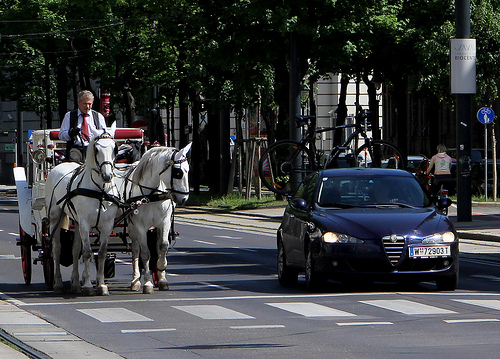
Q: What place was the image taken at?
A: It was taken at the road.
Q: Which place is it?
A: It is a road.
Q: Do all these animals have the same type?
A: Yes, all the animals are horses.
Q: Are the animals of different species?
A: No, all the animals are horses.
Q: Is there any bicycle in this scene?
A: Yes, there is a bicycle.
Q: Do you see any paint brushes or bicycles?
A: Yes, there is a bicycle.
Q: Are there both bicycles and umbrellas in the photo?
A: No, there is a bicycle but no umbrellas.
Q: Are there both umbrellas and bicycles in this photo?
A: No, there is a bicycle but no umbrellas.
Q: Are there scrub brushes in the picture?
A: No, there are no scrub brushes.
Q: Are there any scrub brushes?
A: No, there are no scrub brushes.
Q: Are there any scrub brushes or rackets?
A: No, there are no scrub brushes or rackets.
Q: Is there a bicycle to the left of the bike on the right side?
A: Yes, there is a bicycle to the left of the bike.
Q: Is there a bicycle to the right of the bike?
A: No, the bicycle is to the left of the bike.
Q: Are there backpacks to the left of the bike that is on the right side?
A: No, there is a bicycle to the left of the bike.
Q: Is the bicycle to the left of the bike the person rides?
A: Yes, the bicycle is to the left of the bike.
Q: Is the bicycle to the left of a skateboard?
A: No, the bicycle is to the left of the bike.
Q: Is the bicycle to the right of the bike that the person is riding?
A: No, the bicycle is to the left of the bike.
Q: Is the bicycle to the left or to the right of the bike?
A: The bicycle is to the left of the bike.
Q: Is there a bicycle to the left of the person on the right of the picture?
A: Yes, there is a bicycle to the left of the person.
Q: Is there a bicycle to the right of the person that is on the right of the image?
A: No, the bicycle is to the left of the person.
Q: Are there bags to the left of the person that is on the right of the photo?
A: No, there is a bicycle to the left of the person.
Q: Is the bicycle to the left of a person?
A: Yes, the bicycle is to the left of a person.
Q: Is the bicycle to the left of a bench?
A: No, the bicycle is to the left of a person.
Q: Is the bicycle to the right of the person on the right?
A: No, the bicycle is to the left of the person.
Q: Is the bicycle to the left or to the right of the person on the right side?
A: The bicycle is to the left of the person.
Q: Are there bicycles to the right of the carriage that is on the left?
A: Yes, there is a bicycle to the right of the carriage.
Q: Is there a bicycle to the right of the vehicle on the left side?
A: Yes, there is a bicycle to the right of the carriage.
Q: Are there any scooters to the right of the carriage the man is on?
A: No, there is a bicycle to the right of the carriage.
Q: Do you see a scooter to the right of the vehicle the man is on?
A: No, there is a bicycle to the right of the carriage.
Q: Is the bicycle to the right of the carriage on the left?
A: Yes, the bicycle is to the right of the carriage.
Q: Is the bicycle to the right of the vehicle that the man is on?
A: Yes, the bicycle is to the right of the carriage.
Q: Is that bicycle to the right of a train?
A: No, the bicycle is to the right of the carriage.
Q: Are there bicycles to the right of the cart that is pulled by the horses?
A: Yes, there is a bicycle to the right of the cart.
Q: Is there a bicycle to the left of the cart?
A: No, the bicycle is to the right of the cart.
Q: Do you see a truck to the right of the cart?
A: No, there is a bicycle to the right of the cart.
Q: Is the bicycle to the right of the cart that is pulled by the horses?
A: Yes, the bicycle is to the right of the cart.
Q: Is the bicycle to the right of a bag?
A: No, the bicycle is to the right of the cart.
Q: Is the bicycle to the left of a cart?
A: No, the bicycle is to the right of a cart.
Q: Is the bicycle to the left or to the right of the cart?
A: The bicycle is to the right of the cart.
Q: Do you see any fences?
A: No, there are no fences.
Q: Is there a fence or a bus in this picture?
A: No, there are no fences or buses.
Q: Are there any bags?
A: No, there are no bags.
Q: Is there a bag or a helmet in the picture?
A: No, there are no bags or helmets.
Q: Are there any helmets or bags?
A: No, there are no bags or helmets.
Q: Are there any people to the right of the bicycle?
A: Yes, there is a person to the right of the bicycle.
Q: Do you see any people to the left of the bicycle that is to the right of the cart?
A: No, the person is to the right of the bicycle.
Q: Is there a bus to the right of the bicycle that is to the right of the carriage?
A: No, there is a person to the right of the bicycle.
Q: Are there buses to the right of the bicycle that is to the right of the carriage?
A: No, there is a person to the right of the bicycle.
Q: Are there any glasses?
A: No, there are no glasses.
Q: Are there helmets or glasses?
A: No, there are no glasses or helmets.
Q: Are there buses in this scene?
A: No, there are no buses.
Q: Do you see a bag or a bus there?
A: No, there are no buses or bags.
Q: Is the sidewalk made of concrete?
A: Yes, the sidewalk is made of concrete.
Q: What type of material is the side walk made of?
A: The side walk is made of cement.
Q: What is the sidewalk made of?
A: The side walk is made of concrete.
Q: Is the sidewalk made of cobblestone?
A: No, the sidewalk is made of concrete.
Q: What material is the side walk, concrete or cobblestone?
A: The side walk is made of concrete.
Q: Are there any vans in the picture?
A: No, there are no vans.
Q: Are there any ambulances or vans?
A: No, there are no vans or ambulances.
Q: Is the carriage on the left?
A: Yes, the carriage is on the left of the image.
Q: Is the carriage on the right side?
A: No, the carriage is on the left of the image.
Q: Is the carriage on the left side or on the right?
A: The carriage is on the left of the image.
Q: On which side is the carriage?
A: The carriage is on the left of the image.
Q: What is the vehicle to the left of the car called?
A: The vehicle is a carriage.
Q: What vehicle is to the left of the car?
A: The vehicle is a carriage.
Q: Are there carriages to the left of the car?
A: Yes, there is a carriage to the left of the car.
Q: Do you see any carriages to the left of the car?
A: Yes, there is a carriage to the left of the car.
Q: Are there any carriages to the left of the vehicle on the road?
A: Yes, there is a carriage to the left of the car.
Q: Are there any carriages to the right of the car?
A: No, the carriage is to the left of the car.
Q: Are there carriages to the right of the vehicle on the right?
A: No, the carriage is to the left of the car.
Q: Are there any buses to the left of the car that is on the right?
A: No, there is a carriage to the left of the car.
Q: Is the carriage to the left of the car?
A: Yes, the carriage is to the left of the car.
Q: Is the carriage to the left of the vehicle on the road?
A: Yes, the carriage is to the left of the car.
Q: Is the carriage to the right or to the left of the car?
A: The carriage is to the left of the car.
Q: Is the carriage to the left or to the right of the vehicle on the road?
A: The carriage is to the left of the car.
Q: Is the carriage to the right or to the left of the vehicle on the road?
A: The carriage is to the left of the car.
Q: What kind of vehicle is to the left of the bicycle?
A: The vehicle is a carriage.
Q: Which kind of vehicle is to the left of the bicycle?
A: The vehicle is a carriage.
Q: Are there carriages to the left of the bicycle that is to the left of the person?
A: Yes, there is a carriage to the left of the bicycle.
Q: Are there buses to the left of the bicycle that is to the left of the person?
A: No, there is a carriage to the left of the bicycle.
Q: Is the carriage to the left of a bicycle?
A: Yes, the carriage is to the left of a bicycle.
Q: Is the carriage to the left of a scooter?
A: No, the carriage is to the left of a bicycle.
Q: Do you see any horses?
A: Yes, there are horses.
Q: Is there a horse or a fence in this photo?
A: Yes, there are horses.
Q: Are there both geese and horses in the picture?
A: No, there are horses but no geese.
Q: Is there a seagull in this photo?
A: No, there are no seagulls.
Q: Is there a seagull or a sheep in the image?
A: No, there are no seagulls or sheep.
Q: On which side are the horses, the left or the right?
A: The horses are on the left of the image.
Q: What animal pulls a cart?
A: The horses pull a cart.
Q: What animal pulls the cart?
A: The horses pull a cart.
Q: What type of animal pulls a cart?
A: The animals are horses.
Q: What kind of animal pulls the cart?
A: The animals are horses.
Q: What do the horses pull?
A: The horses pull a cart.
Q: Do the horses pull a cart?
A: Yes, the horses pull a cart.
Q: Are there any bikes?
A: Yes, there is a bike.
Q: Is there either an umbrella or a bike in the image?
A: Yes, there is a bike.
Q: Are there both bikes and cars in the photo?
A: Yes, there are both a bike and a car.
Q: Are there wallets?
A: No, there are no wallets.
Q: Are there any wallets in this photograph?
A: No, there are no wallets.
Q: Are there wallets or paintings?
A: No, there are no wallets or paintings.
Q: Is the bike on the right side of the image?
A: Yes, the bike is on the right of the image.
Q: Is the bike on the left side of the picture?
A: No, the bike is on the right of the image.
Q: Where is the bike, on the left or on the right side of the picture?
A: The bike is on the right of the image.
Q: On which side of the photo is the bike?
A: The bike is on the right of the image.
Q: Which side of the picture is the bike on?
A: The bike is on the right of the image.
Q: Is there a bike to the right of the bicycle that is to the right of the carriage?
A: Yes, there is a bike to the right of the bicycle.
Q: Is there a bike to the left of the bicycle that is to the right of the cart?
A: No, the bike is to the right of the bicycle.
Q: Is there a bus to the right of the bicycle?
A: No, there is a bike to the right of the bicycle.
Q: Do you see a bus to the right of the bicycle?
A: No, there is a bike to the right of the bicycle.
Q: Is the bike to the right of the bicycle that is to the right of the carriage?
A: Yes, the bike is to the right of the bicycle.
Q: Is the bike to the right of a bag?
A: No, the bike is to the right of the bicycle.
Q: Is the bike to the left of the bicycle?
A: No, the bike is to the right of the bicycle.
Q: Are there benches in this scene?
A: No, there are no benches.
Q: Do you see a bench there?
A: No, there are no benches.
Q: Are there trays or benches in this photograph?
A: No, there are no benches or trays.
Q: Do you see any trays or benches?
A: No, there are no benches or trays.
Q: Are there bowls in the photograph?
A: No, there are no bowls.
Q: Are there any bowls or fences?
A: No, there are no bowls or fences.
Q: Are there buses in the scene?
A: No, there are no buses.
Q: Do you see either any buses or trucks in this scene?
A: No, there are no buses or trucks.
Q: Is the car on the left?
A: No, the car is on the right of the image.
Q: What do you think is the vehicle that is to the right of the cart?
A: The vehicle is a car.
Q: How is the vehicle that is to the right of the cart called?
A: The vehicle is a car.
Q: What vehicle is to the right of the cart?
A: The vehicle is a car.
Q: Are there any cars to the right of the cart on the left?
A: Yes, there is a car to the right of the cart.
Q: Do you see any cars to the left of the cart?
A: No, the car is to the right of the cart.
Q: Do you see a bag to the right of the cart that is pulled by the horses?
A: No, there is a car to the right of the cart.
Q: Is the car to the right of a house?
A: No, the car is to the right of the cart.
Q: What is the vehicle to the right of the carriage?
A: The vehicle is a car.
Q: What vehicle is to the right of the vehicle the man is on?
A: The vehicle is a car.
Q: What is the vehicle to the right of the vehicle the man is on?
A: The vehicle is a car.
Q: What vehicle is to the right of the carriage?
A: The vehicle is a car.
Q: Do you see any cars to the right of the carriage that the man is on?
A: Yes, there is a car to the right of the carriage.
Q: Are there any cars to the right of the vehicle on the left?
A: Yes, there is a car to the right of the carriage.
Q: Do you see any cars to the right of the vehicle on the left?
A: Yes, there is a car to the right of the carriage.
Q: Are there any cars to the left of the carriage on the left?
A: No, the car is to the right of the carriage.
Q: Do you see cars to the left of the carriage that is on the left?
A: No, the car is to the right of the carriage.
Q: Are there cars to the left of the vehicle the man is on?
A: No, the car is to the right of the carriage.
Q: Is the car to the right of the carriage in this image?
A: Yes, the car is to the right of the carriage.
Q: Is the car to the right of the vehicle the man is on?
A: Yes, the car is to the right of the carriage.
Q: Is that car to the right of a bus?
A: No, the car is to the right of the carriage.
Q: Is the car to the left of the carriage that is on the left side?
A: No, the car is to the right of the carriage.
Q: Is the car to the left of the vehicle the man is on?
A: No, the car is to the right of the carriage.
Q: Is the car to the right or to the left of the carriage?
A: The car is to the right of the carriage.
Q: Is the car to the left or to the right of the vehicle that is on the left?
A: The car is to the right of the carriage.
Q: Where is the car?
A: The car is on the road.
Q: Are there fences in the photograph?
A: No, there are no fences.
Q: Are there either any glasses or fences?
A: No, there are no fences or glasses.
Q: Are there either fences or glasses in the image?
A: No, there are no fences or glasses.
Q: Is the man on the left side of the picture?
A: Yes, the man is on the left of the image.